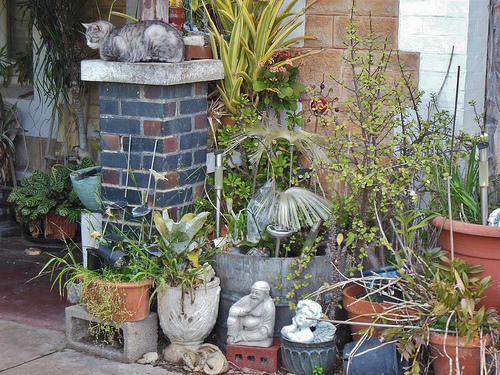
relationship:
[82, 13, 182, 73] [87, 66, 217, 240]
cat on pillar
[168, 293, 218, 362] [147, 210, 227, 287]
vase with plant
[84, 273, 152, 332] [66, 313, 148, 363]
plant on cement stone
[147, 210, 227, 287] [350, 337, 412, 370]
plant in flower pot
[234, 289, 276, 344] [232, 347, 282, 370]
budda on brick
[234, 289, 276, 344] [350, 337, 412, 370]
graden statue in a flower pot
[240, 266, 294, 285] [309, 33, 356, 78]
stone structure by wall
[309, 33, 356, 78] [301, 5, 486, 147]
wall on building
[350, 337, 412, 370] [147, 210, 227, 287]
flower pot with plant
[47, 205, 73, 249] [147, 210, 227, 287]
clay pot with plant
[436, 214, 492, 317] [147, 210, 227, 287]
large flowerpot with plant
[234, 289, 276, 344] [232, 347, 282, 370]
graden statue on brick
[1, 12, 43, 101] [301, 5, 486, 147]
window of building